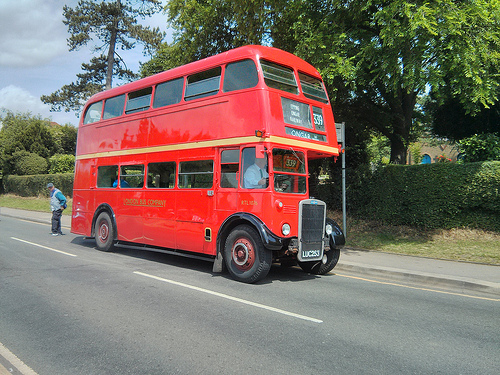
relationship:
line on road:
[104, 252, 324, 364] [30, 208, 168, 346]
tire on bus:
[80, 211, 137, 254] [68, 63, 378, 276]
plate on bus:
[294, 245, 325, 259] [68, 63, 378, 276]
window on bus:
[178, 155, 219, 194] [68, 63, 378, 276]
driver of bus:
[246, 146, 271, 190] [68, 63, 378, 276]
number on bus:
[312, 111, 334, 132] [68, 63, 378, 276]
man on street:
[34, 183, 68, 239] [41, 225, 79, 372]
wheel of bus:
[224, 200, 268, 280] [68, 63, 378, 276]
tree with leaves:
[290, 16, 459, 187] [426, 3, 499, 102]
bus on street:
[68, 63, 378, 276] [41, 225, 79, 372]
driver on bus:
[246, 146, 271, 190] [68, 63, 378, 276]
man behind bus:
[34, 183, 68, 239] [68, 63, 378, 276]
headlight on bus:
[273, 219, 307, 256] [68, 63, 378, 276]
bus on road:
[68, 63, 378, 276] [30, 208, 168, 346]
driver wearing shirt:
[246, 146, 271, 190] [242, 161, 266, 188]